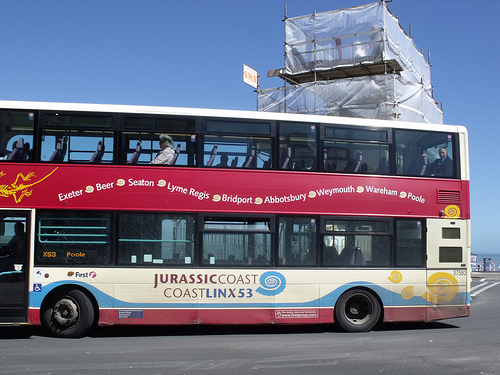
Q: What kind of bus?
A: Double decker tourist bus.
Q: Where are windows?
A: On the bus.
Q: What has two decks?
A: The bus.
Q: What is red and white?
A: The bus.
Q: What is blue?
A: Sky.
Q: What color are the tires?
A: Black.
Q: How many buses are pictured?
A: One.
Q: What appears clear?
A: The sky.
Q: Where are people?
A: In the bus.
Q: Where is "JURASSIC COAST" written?
A: On side of bus.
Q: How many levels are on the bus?
A: Two.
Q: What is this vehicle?
A: A bus.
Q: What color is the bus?
A: Red and white.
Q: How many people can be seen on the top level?
A: Two.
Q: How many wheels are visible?
A: Two.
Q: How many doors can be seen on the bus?
A: One.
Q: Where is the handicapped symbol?
A: Near the bus door.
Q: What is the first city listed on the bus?
A: Exeter.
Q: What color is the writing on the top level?
A: White and yellow.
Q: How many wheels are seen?
A: 2.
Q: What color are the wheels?
A: Black.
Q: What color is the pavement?
A: Gray.